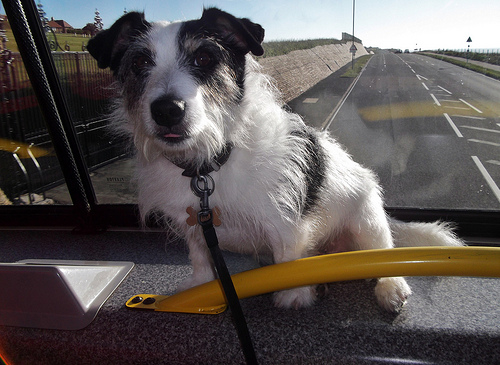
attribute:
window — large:
[37, 10, 497, 226]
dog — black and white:
[118, 35, 265, 150]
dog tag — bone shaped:
[182, 203, 225, 230]